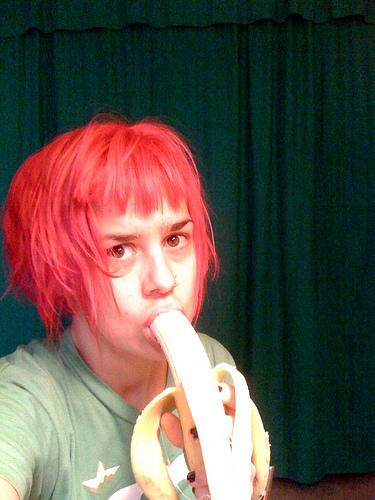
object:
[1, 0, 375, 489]
drapes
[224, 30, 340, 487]
pleats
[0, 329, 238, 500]
shirt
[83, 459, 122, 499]
logo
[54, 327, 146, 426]
collar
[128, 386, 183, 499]
peel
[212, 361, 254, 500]
peel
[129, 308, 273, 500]
banana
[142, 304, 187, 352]
mouth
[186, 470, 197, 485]
nail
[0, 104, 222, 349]
hair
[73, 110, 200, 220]
bangs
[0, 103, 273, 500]
woman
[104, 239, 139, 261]
brown eyes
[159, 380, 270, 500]
left hand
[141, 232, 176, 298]
nose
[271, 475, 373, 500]
wood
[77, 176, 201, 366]
face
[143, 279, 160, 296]
nostril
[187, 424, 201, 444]
fingernail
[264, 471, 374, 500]
floor